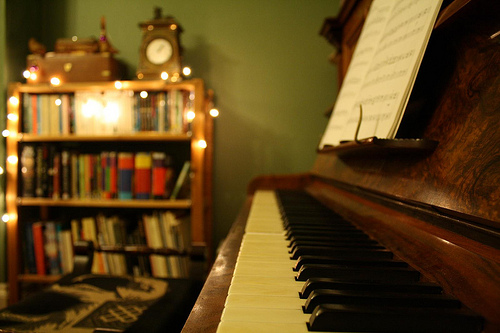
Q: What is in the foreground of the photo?
A: Piano.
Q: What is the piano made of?
A: Wood.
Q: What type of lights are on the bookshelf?
A: Christmas lights.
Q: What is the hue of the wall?
A: Green.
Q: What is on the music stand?
A: Sheet music.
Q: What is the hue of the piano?
A: Brown.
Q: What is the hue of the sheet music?
A: White.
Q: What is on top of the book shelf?
A: Clock.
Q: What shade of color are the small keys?
A: Black.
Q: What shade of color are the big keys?
A: White.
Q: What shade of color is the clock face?
A: White.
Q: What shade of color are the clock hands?
A: Black.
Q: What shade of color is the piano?
A: Brown.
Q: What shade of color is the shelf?
A: Brown.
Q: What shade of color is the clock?
A: Brown.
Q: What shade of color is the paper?
A: White.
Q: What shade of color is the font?
A: Black.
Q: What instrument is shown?
A: A piano.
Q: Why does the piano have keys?
A: To play music.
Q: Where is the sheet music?
A: Above the keyboard.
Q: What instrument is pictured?
A: Piano.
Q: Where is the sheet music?
A: On the piano's ledge.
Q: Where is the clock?
A: On top of the bookshelf.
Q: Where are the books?
A: In the bookshelf.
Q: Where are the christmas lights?
A: Around the bookshelf.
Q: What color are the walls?
A: Green.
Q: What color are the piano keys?
A: White and black.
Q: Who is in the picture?
A: There are no people in the image.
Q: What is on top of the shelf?
A: A clock.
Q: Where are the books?
A: On the shelf.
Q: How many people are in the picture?
A: Zero.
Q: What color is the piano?
A: Brown.